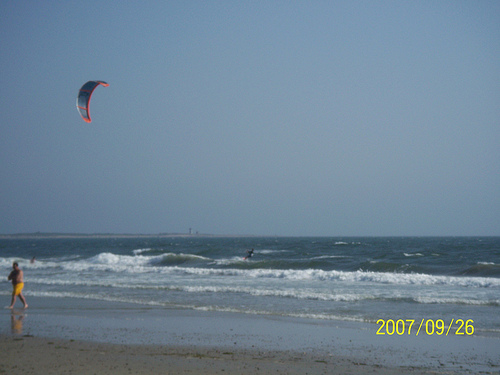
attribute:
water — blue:
[0, 235, 495, 305]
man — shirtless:
[5, 261, 27, 310]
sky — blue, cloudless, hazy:
[0, 0, 499, 234]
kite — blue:
[28, 45, 170, 182]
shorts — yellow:
[8, 279, 26, 298]